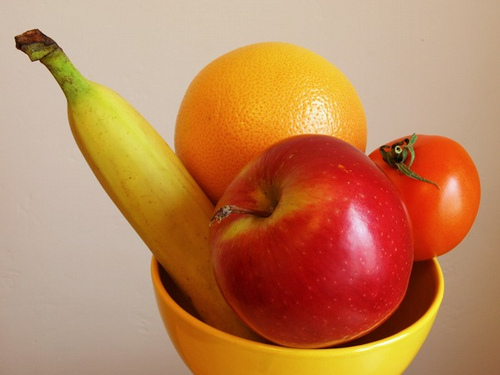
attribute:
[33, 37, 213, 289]
banana — unpeeled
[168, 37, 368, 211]
orange — unpeeled., round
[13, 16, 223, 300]
banana — ripe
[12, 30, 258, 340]
banana — yellow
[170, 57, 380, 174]
fruit — in a bowl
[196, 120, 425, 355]
apple — unpeeled., red, ripe, round